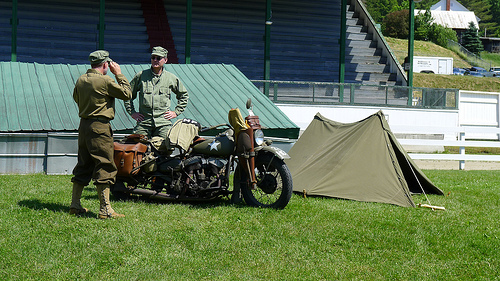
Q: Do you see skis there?
A: No, there are no skis.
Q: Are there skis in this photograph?
A: No, there are no skis.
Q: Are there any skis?
A: No, there are no skis.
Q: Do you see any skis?
A: No, there are no skis.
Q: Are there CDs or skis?
A: No, there are no skis or cds.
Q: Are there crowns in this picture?
A: No, there are no crowns.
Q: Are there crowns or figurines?
A: No, there are no crowns or figurines.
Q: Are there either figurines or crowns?
A: No, there are no crowns or figurines.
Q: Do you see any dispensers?
A: No, there are no dispensers.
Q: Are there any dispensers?
A: No, there are no dispensers.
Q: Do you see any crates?
A: No, there are no crates.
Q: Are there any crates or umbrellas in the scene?
A: No, there are no crates or umbrellas.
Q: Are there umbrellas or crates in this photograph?
A: No, there are no crates or umbrellas.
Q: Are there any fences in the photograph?
A: Yes, there is a fence.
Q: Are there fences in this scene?
A: Yes, there is a fence.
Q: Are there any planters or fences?
A: Yes, there is a fence.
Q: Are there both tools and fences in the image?
A: No, there is a fence but no tools.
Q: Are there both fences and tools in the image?
A: No, there is a fence but no tools.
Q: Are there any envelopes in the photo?
A: No, there are no envelopes.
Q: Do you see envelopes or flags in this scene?
A: No, there are no envelopes or flags.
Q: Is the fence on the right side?
A: Yes, the fence is on the right of the image.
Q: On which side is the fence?
A: The fence is on the right of the image.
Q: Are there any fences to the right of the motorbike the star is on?
A: Yes, there is a fence to the right of the motorcycle.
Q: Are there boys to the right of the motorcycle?
A: No, there is a fence to the right of the motorcycle.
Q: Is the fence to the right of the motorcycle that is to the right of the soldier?
A: Yes, the fence is to the right of the motorbike.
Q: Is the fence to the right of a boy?
A: No, the fence is to the right of the motorbike.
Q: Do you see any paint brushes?
A: No, there are no paint brushes.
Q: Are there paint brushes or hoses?
A: No, there are no paint brushes or hoses.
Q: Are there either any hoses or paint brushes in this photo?
A: No, there are no paint brushes or hoses.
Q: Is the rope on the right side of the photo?
A: Yes, the rope is on the right of the image.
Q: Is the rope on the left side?
A: No, the rope is on the right of the image.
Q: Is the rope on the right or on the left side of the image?
A: The rope is on the right of the image.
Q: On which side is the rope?
A: The rope is on the right of the image.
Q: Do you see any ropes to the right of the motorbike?
A: Yes, there is a rope to the right of the motorbike.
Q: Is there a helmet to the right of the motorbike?
A: No, there is a rope to the right of the motorbike.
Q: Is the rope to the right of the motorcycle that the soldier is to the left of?
A: Yes, the rope is to the right of the motorbike.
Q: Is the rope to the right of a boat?
A: No, the rope is to the right of the motorbike.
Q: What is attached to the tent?
A: The rope is attached to the tent.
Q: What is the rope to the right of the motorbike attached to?
A: The rope is attached to the tent.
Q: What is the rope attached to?
A: The rope is attached to the tent.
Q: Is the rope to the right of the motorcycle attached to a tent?
A: Yes, the rope is attached to a tent.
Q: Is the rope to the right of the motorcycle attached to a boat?
A: No, the rope is attached to a tent.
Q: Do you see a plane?
A: No, there are no airplanes.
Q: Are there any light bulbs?
A: No, there are no light bulbs.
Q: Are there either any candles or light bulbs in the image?
A: No, there are no light bulbs or candles.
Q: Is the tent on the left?
A: No, the tent is on the right of the image.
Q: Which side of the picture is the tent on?
A: The tent is on the right of the image.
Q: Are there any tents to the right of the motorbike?
A: Yes, there is a tent to the right of the motorbike.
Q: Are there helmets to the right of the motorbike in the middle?
A: No, there is a tent to the right of the motorcycle.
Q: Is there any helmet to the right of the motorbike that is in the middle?
A: No, there is a tent to the right of the motorcycle.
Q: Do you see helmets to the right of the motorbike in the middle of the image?
A: No, there is a tent to the right of the motorcycle.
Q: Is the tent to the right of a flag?
A: No, the tent is to the right of a motorcycle.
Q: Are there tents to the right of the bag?
A: Yes, there is a tent to the right of the bag.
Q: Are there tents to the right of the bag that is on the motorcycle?
A: Yes, there is a tent to the right of the bag.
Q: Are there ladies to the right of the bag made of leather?
A: No, there is a tent to the right of the bag.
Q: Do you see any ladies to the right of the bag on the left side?
A: No, there is a tent to the right of the bag.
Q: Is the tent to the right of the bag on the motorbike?
A: Yes, the tent is to the right of the bag.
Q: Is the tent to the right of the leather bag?
A: Yes, the tent is to the right of the bag.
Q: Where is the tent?
A: The tent is on the grass.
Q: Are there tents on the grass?
A: Yes, there is a tent on the grass.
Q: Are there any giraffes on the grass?
A: No, there is a tent on the grass.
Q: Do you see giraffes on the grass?
A: No, there is a tent on the grass.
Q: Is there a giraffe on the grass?
A: No, there is a tent on the grass.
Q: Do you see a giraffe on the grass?
A: No, there is a tent on the grass.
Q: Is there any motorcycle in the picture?
A: Yes, there is a motorcycle.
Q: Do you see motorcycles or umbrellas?
A: Yes, there is a motorcycle.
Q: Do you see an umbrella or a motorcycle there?
A: Yes, there is a motorcycle.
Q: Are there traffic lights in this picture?
A: No, there are no traffic lights.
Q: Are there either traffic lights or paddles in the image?
A: No, there are no traffic lights or paddles.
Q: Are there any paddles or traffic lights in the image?
A: No, there are no traffic lights or paddles.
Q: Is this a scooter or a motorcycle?
A: This is a motorcycle.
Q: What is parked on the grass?
A: The motorbike is parked on the grass.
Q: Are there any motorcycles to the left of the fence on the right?
A: Yes, there is a motorcycle to the left of the fence.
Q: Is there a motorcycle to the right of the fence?
A: No, the motorcycle is to the left of the fence.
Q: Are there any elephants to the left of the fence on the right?
A: No, there is a motorcycle to the left of the fence.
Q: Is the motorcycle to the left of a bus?
A: No, the motorcycle is to the left of the fence.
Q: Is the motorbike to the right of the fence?
A: No, the motorbike is to the left of the fence.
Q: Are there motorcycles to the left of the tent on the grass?
A: Yes, there is a motorcycle to the left of the tent.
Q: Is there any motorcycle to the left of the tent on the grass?
A: Yes, there is a motorcycle to the left of the tent.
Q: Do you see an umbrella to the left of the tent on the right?
A: No, there is a motorcycle to the left of the tent.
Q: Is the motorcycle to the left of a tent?
A: Yes, the motorcycle is to the left of a tent.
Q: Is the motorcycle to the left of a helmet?
A: No, the motorcycle is to the left of a tent.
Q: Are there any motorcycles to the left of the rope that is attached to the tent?
A: Yes, there is a motorcycle to the left of the rope.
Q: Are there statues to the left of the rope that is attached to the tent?
A: No, there is a motorcycle to the left of the rope.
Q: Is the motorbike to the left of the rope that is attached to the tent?
A: Yes, the motorbike is to the left of the rope.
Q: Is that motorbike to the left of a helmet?
A: No, the motorbike is to the left of the rope.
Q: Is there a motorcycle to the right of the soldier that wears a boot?
A: Yes, there is a motorcycle to the right of the soldier.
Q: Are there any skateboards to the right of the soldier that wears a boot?
A: No, there is a motorcycle to the right of the soldier.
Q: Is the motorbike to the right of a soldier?
A: Yes, the motorbike is to the right of a soldier.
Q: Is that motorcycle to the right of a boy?
A: No, the motorcycle is to the right of a soldier.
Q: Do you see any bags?
A: Yes, there is a bag.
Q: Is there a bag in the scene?
A: Yes, there is a bag.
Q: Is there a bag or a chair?
A: Yes, there is a bag.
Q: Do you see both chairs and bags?
A: No, there is a bag but no chairs.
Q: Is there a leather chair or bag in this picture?
A: Yes, there is a leather bag.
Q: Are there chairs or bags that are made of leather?
A: Yes, the bag is made of leather.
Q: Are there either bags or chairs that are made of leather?
A: Yes, the bag is made of leather.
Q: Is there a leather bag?
A: Yes, there is a bag that is made of leather.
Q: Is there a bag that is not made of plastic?
A: Yes, there is a bag that is made of leather.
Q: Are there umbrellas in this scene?
A: No, there are no umbrellas.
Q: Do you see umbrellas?
A: No, there are no umbrellas.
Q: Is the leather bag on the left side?
A: Yes, the bag is on the left of the image.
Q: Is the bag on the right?
A: No, the bag is on the left of the image.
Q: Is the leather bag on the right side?
A: No, the bag is on the left of the image.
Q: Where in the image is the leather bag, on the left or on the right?
A: The bag is on the left of the image.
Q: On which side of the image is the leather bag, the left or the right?
A: The bag is on the left of the image.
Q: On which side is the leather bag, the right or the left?
A: The bag is on the left of the image.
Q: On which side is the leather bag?
A: The bag is on the left of the image.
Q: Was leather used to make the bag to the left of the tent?
A: Yes, the bag is made of leather.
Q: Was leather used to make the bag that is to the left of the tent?
A: Yes, the bag is made of leather.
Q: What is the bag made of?
A: The bag is made of leather.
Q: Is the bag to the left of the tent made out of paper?
A: No, the bag is made of leather.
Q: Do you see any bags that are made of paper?
A: No, there is a bag but it is made of leather.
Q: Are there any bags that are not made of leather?
A: No, there is a bag but it is made of leather.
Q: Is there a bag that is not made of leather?
A: No, there is a bag but it is made of leather.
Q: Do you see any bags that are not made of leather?
A: No, there is a bag but it is made of leather.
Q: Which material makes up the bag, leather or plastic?
A: The bag is made of leather.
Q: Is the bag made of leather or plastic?
A: The bag is made of leather.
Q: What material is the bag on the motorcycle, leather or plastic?
A: The bag is made of leather.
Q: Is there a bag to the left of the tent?
A: Yes, there is a bag to the left of the tent.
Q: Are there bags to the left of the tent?
A: Yes, there is a bag to the left of the tent.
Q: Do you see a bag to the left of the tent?
A: Yes, there is a bag to the left of the tent.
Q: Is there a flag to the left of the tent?
A: No, there is a bag to the left of the tent.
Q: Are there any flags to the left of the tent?
A: No, there is a bag to the left of the tent.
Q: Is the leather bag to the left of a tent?
A: Yes, the bag is to the left of a tent.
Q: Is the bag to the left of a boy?
A: No, the bag is to the left of a tent.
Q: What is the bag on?
A: The bag is on the motorbike.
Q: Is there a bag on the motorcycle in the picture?
A: Yes, there is a bag on the motorcycle.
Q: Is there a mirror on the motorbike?
A: No, there is a bag on the motorbike.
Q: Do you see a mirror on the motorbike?
A: No, there is a bag on the motorbike.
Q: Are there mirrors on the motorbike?
A: No, there is a bag on the motorbike.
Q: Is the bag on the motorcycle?
A: Yes, the bag is on the motorcycle.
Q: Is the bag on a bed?
A: No, the bag is on the motorcycle.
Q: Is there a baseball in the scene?
A: No, there are no baseballs.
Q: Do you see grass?
A: Yes, there is grass.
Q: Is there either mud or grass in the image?
A: Yes, there is grass.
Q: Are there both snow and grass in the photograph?
A: No, there is grass but no snow.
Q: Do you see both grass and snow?
A: No, there is grass but no snow.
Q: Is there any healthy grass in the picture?
A: Yes, there is healthy grass.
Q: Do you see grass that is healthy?
A: Yes, there is grass that is healthy.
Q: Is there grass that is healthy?
A: Yes, there is grass that is healthy.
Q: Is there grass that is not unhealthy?
A: Yes, there is healthy grass.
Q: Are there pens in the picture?
A: No, there are no pens.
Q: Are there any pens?
A: No, there are no pens.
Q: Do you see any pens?
A: No, there are no pens.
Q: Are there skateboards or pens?
A: No, there are no pens or skateboards.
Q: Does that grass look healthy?
A: Yes, the grass is healthy.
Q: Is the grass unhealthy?
A: No, the grass is healthy.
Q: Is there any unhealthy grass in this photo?
A: No, there is grass but it is healthy.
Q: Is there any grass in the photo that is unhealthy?
A: No, there is grass but it is healthy.